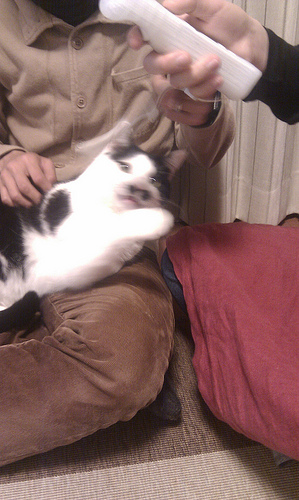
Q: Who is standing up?
A: No one.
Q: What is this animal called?
A: Cat.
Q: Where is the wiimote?
A: In the hand.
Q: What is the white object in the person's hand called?
A: Wiimote.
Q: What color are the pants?
A: Brown.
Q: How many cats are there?
A: One.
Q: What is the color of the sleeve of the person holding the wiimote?
A: Black.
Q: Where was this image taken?
A: On floor.